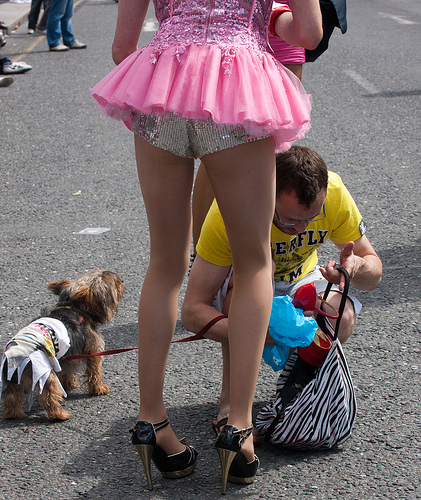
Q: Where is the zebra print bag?
A: On the pavement.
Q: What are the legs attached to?
A: Two shoes high heels.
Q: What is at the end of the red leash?
A: Small brown dog.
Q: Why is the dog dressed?
A: Owner did it.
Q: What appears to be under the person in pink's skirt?
A: Shorts.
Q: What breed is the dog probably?
A: Terrier.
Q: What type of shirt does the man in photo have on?
A: Yellow t-shirt.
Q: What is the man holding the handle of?
A: Bag.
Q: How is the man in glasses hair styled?
A: Short.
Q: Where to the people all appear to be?
A: In street.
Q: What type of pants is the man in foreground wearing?
A: Shorts.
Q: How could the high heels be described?
A: Platform sole.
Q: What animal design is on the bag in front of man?
A: Zebra.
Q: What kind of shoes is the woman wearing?
A: Heels.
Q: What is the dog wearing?
A: Clothing.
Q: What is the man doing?
A: Looking in purse.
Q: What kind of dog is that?
A: Yorkshire Terrier.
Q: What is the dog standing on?
A: Pavement.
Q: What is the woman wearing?
A: A dress.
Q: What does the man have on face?
A: Glasses.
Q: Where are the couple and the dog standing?
A: The road.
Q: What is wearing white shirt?
A: The dog.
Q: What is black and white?
A: A zebra bag.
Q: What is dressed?
A: The dog.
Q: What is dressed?
A: The dog.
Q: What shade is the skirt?
A: Pink.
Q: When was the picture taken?
A: Parade.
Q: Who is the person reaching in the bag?
A: Dog Owner.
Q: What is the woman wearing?
A: Tutu.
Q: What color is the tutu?
A: Pink.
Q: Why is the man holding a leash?
A: Dog.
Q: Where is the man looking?
A: Purse.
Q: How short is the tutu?
A: Short.